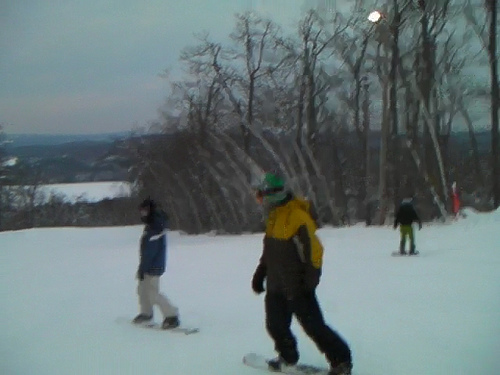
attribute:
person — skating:
[129, 195, 181, 329]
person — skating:
[249, 175, 344, 374]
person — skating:
[393, 199, 422, 253]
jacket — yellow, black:
[260, 203, 328, 293]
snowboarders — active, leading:
[116, 191, 451, 375]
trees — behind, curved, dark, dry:
[2, 0, 499, 226]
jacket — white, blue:
[135, 214, 166, 275]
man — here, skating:
[134, 192, 174, 327]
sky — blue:
[6, 0, 495, 136]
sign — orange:
[449, 184, 465, 215]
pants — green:
[400, 226, 420, 253]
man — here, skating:
[397, 199, 425, 258]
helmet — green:
[256, 173, 291, 208]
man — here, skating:
[259, 181, 343, 372]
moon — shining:
[358, 9, 387, 28]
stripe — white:
[140, 225, 171, 244]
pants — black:
[260, 284, 354, 368]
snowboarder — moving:
[396, 198, 424, 252]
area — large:
[1, 175, 135, 211]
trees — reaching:
[310, 4, 374, 225]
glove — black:
[253, 266, 274, 295]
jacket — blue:
[392, 206, 421, 231]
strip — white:
[146, 229, 168, 249]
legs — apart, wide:
[257, 285, 349, 374]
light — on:
[358, 11, 391, 24]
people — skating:
[134, 172, 423, 374]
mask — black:
[140, 201, 154, 224]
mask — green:
[401, 197, 412, 203]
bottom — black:
[256, 223, 330, 294]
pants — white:
[137, 268, 178, 325]